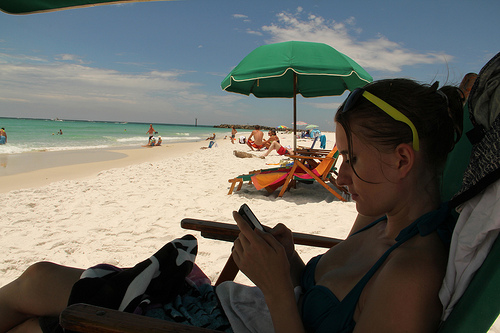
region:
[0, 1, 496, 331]
People sitting on a beach.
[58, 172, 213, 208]
The sand is biege.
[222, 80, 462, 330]
The woman is looking at her phone.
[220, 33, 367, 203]
The umbrella is green.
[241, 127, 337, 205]
A lounge chair under the umbrella.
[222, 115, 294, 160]
People are sitting on the beach.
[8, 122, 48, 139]
The water is acqua color.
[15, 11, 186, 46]
The sky is blue.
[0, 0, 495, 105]
Clouds in the sky.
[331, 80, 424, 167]
The woman has sunglasses on her head.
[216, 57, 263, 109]
a green umbrella at the beach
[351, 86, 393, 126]
a girl wearing sun glasses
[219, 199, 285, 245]
a girl on her phone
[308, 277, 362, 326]
a girl wearing a black bikini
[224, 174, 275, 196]
a orange chair near the girl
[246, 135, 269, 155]
a boy in orange shorts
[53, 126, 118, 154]
water at the beach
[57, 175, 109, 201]
sand at the beach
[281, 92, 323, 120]
a pole holding the umbrella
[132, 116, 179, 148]
a boy in the distance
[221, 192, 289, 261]
A girl on the cellphone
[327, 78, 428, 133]
Sunglasses on top of woman head.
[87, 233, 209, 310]
The woman has towel in her lap.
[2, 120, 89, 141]
People in the water.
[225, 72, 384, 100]
A green umbrella on th beach.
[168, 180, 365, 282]
The woman is texting on cellphone.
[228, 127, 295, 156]
People sitting on the sand.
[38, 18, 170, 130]
The sky is clear and blue.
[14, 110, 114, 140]
The water is green and blue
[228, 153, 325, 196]
A towel on the beach chair.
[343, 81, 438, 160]
yellow frame of sunglasses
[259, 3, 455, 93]
cloud in the sky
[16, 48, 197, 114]
clouds in the sky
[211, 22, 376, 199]
large green beach umbrella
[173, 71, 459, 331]
woman looking at cellphone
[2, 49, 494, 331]
woman sitting near the beach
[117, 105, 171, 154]
people in the water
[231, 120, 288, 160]
people sitting in the sand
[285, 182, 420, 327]
woman wearing a swimsuit top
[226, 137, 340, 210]
long beach towel on chair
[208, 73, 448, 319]
a woman looking at her cellphone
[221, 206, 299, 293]
the hands of a woman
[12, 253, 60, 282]
the knee of a woman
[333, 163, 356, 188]
the nose of a woman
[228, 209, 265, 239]
the finger of a woman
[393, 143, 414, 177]
the ear of a woman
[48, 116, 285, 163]
several people on the beach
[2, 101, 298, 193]
several people at the beach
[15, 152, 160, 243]
the white sand of a beach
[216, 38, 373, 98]
a green umbrella